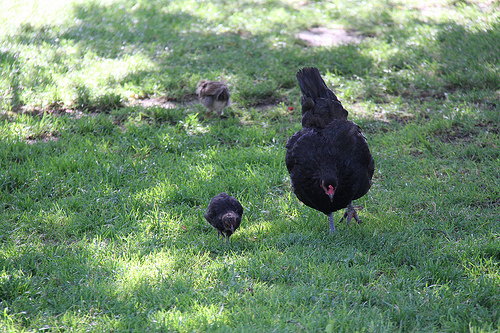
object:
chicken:
[203, 192, 244, 244]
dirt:
[1, 90, 193, 121]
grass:
[113, 149, 157, 200]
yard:
[0, 0, 500, 333]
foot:
[326, 227, 341, 237]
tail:
[216, 191, 230, 197]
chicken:
[284, 66, 376, 237]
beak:
[327, 194, 336, 203]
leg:
[225, 232, 232, 242]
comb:
[328, 184, 334, 196]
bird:
[194, 79, 232, 120]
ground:
[60, 177, 187, 301]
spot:
[81, 204, 126, 244]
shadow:
[47, 95, 105, 129]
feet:
[338, 209, 364, 227]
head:
[222, 211, 237, 234]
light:
[68, 60, 108, 88]